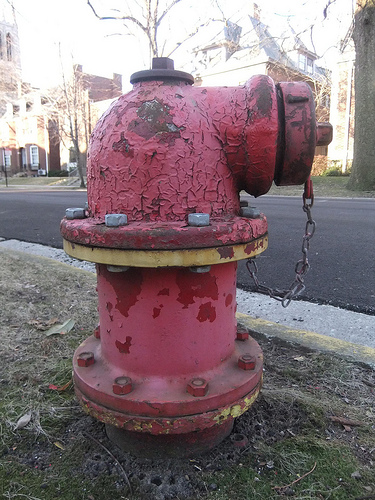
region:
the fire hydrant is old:
[32, 45, 347, 433]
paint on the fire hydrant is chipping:
[58, 55, 323, 482]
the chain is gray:
[240, 203, 332, 321]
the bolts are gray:
[53, 197, 273, 237]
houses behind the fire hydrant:
[1, 34, 372, 184]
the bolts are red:
[60, 314, 288, 409]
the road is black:
[3, 175, 373, 329]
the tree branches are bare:
[82, 0, 373, 91]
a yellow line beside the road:
[4, 235, 373, 387]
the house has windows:
[1, 138, 47, 189]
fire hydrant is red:
[47, 41, 346, 450]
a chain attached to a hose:
[247, 200, 330, 322]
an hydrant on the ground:
[52, 31, 359, 459]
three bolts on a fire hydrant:
[53, 199, 220, 234]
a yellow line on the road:
[253, 312, 373, 365]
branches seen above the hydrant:
[86, 2, 332, 57]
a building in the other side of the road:
[0, 58, 85, 173]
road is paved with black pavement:
[264, 199, 370, 309]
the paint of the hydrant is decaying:
[42, 32, 353, 454]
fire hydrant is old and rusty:
[39, 42, 341, 467]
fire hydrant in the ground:
[55, 55, 336, 462]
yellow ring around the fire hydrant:
[60, 237, 281, 271]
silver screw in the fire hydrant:
[100, 211, 131, 276]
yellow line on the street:
[240, 307, 372, 364]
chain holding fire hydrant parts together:
[244, 183, 319, 308]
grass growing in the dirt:
[224, 445, 359, 495]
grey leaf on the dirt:
[41, 316, 78, 337]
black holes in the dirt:
[130, 466, 180, 488]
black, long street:
[2, 184, 373, 318]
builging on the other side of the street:
[0, 0, 110, 189]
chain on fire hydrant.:
[297, 226, 312, 269]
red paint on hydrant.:
[153, 320, 189, 349]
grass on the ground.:
[283, 448, 323, 476]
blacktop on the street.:
[353, 208, 368, 233]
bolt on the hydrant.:
[185, 212, 205, 227]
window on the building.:
[27, 144, 36, 166]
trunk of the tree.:
[357, 59, 372, 164]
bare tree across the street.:
[58, 80, 81, 158]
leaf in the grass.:
[49, 312, 74, 337]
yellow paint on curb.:
[304, 338, 360, 359]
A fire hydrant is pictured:
[21, 40, 348, 461]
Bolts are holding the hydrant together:
[102, 210, 220, 283]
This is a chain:
[268, 196, 325, 307]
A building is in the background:
[2, 83, 89, 190]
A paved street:
[2, 174, 59, 255]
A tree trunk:
[346, 8, 373, 209]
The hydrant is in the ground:
[42, 317, 301, 485]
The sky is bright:
[25, 6, 123, 62]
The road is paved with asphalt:
[318, 222, 373, 320]